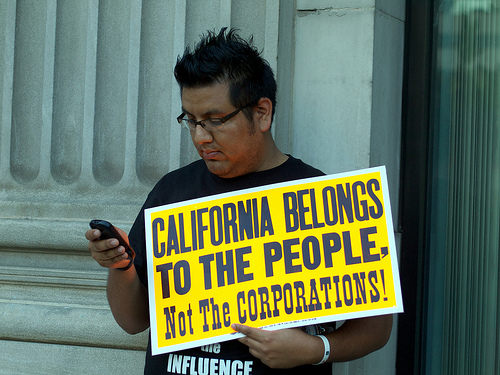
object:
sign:
[144, 165, 406, 358]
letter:
[155, 262, 174, 300]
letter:
[173, 259, 192, 295]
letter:
[234, 246, 254, 283]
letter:
[215, 249, 235, 287]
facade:
[0, 0, 500, 375]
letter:
[301, 235, 322, 270]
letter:
[262, 241, 282, 278]